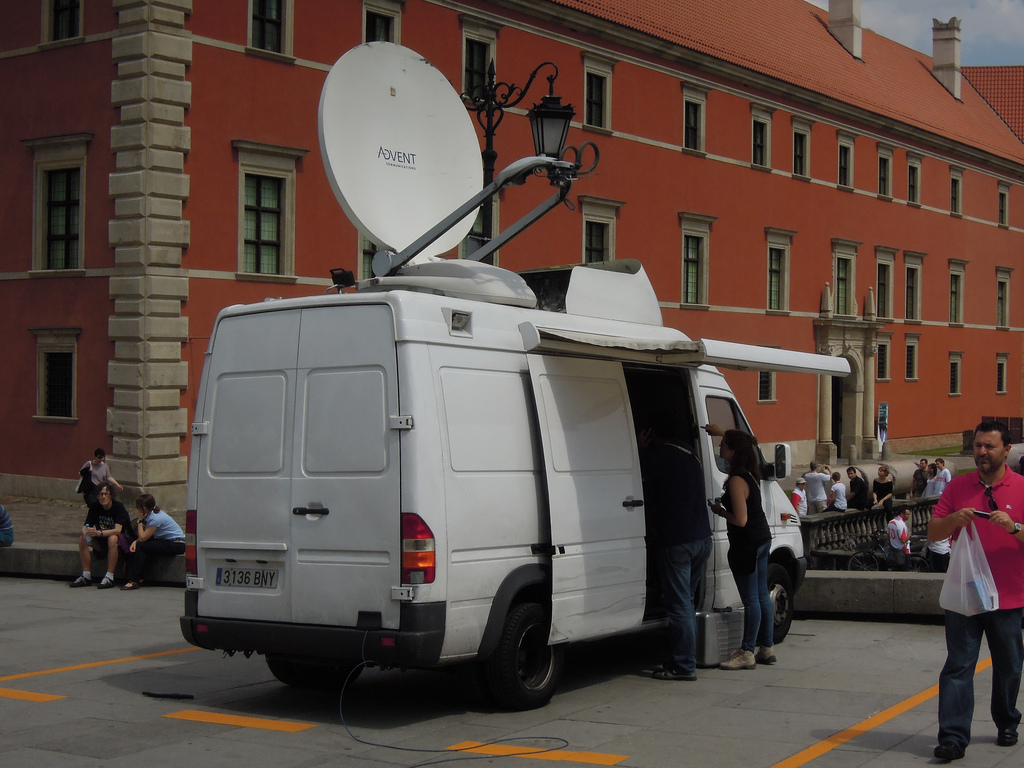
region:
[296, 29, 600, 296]
the satellite dish on the van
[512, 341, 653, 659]
the door of the van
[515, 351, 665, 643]
the door is open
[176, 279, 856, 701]
the van is white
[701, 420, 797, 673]
the woman wearing jeans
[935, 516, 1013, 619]
the bag is plastic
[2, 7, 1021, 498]
the building behind the van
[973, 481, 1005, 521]
sunglasses on the shirt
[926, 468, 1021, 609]
the shirt is pink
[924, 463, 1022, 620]
The red shirt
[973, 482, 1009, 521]
A pair of black sunglasses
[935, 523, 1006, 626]
The white plastic bag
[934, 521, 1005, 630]
A clear white plastic bag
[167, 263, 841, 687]
The white news van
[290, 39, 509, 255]
The white satellite dish on the van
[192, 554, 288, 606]
The license plate on the van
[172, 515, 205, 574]
The left headlight on the van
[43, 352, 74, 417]
window on side of brick building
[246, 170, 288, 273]
window on side of brick building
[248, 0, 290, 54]
window on side of brick building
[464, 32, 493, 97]
window on side of brick building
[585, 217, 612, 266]
window on side of brick building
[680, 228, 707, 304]
window on side of brick building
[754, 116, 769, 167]
window on side of brick building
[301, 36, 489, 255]
satellite dish on top of van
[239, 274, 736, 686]
white communications van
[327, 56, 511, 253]
white satellite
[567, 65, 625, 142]
white window in brick building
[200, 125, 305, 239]
white window in brick building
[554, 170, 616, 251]
white window in brick building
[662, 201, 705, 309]
white window in brick building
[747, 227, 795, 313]
white window in brick building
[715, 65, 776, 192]
white window in brick building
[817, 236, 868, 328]
white window in brick building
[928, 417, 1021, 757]
the man is walking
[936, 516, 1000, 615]
the plastic bag is white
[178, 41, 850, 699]
the van is white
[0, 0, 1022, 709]
the large building behind the van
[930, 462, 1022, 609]
the shirt is pink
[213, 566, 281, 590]
the license plate is black and white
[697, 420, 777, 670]
the woman is wearing blue jeans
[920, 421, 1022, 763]
the man is wearing blue jeans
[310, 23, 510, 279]
a large satellite dish on top of a van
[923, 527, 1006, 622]
an opaque plastic shopping bag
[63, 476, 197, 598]
a pair of teenagers sitting on the curb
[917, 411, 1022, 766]
a man in a bright pink polo shirt